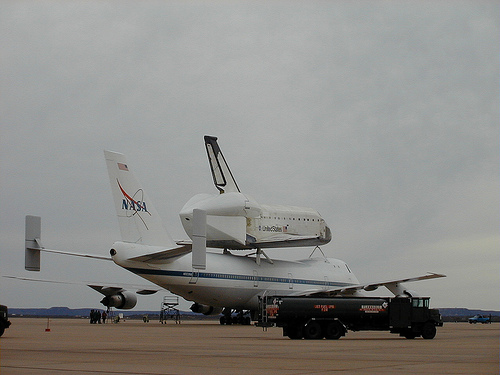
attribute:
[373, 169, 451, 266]
sky — blue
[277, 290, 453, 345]
truck — black, long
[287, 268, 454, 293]
wing — plane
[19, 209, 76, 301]
pole — horizontal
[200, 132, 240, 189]
wing — black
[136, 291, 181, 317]
staircase — for boarding planes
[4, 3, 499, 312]
sky — bright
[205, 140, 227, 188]
rectangle — black, white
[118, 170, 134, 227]
logo — aeronautics organization